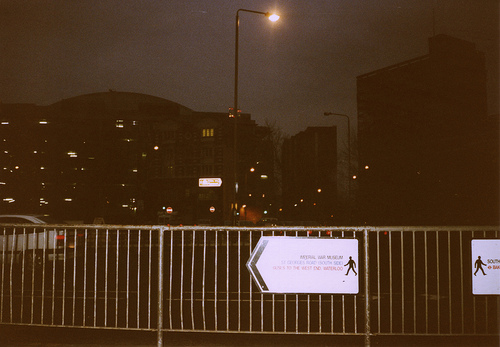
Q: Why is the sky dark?
A: Sun is down.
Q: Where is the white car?
A: Behind the gate.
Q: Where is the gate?
A: In front of the street.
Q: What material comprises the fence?
A: Metal.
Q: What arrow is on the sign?
A: Left arrow.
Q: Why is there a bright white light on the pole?
A: Street light.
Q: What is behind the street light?
A: A large building.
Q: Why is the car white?
A: Paint.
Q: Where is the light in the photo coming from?
A: A thin grey street light.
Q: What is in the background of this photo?
A: A bunch of buildings with lights on.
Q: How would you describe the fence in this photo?
A: A long thin grey fence.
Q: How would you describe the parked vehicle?
A: White.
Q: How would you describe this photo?
A: A dark picture of a bunch of buildings.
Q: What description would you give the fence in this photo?
A: A metal fence with a sign on it.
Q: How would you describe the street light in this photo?
A: A lit lamp.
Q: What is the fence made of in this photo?
A: Iron.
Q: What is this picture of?
A: A city at night.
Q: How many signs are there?
A: 2.